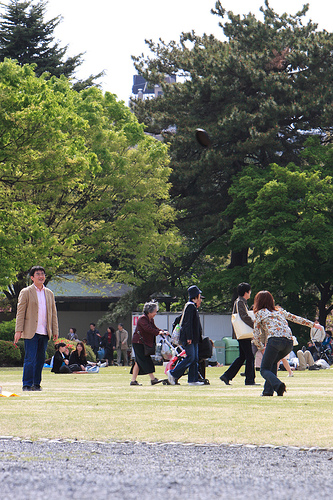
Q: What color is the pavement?
A: Gray.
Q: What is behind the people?
A: Buildings.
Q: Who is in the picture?
A: People.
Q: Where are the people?
A: In a park.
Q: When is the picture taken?
A: Daytime.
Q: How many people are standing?
A: 10.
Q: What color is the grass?
A: Green.